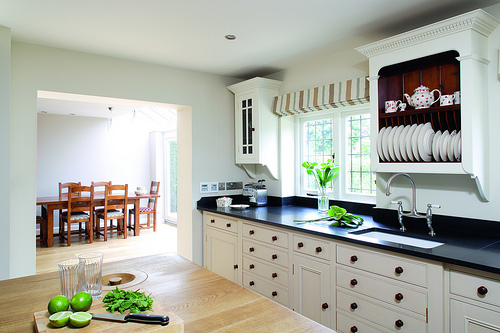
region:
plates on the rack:
[374, 120, 465, 165]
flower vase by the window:
[301, 150, 341, 213]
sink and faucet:
[343, 168, 448, 253]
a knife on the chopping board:
[86, 308, 171, 328]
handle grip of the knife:
[122, 309, 171, 327]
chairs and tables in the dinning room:
[32, 175, 166, 251]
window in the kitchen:
[291, 105, 376, 201]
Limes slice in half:
[46, 290, 95, 331]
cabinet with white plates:
[355, 7, 495, 199]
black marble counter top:
[198, 185, 498, 268]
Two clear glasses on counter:
[58, 247, 100, 297]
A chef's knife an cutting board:
[80, 306, 172, 326]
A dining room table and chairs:
[34, 175, 171, 245]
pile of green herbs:
[105, 285, 153, 321]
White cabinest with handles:
[196, 209, 498, 331]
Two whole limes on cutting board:
[52, 293, 94, 311]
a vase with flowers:
[304, 150, 339, 210]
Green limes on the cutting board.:
[35, 278, 97, 330]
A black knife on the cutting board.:
[92, 308, 180, 332]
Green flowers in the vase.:
[306, 162, 344, 213]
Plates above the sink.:
[369, 123, 459, 162]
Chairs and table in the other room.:
[50, 180, 177, 235]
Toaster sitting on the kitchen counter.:
[236, 179, 279, 213]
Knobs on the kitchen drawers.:
[342, 255, 415, 314]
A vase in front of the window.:
[299, 131, 366, 212]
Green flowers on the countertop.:
[306, 188, 368, 229]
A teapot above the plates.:
[386, 82, 454, 113]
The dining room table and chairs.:
[33, 172, 160, 243]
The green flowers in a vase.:
[302, 153, 344, 181]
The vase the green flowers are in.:
[317, 178, 332, 223]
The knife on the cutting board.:
[83, 309, 171, 326]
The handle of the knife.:
[126, 313, 174, 324]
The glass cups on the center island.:
[57, 255, 102, 300]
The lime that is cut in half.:
[43, 309, 98, 327]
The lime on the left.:
[45, 293, 66, 308]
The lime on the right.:
[73, 290, 95, 305]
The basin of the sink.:
[357, 226, 437, 253]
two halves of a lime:
[45, 308, 92, 328]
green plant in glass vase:
[302, 157, 340, 212]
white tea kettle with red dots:
[404, 78, 441, 110]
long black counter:
[195, 191, 497, 280]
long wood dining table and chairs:
[35, 178, 160, 250]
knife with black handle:
[90, 308, 170, 324]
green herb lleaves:
[102, 285, 154, 312]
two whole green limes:
[46, 290, 94, 312]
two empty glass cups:
[55, 250, 105, 300]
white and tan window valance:
[271, 73, 370, 117]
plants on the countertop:
[285, 200, 374, 244]